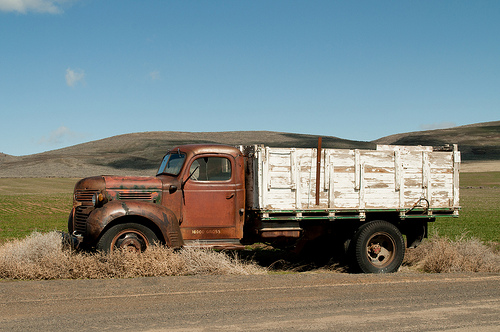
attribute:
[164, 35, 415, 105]
sky — deep, blue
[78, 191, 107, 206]
headlight — old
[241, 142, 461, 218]
truck bed — old, white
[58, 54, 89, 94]
cloud — white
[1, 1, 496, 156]
sky — blue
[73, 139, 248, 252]
cab — orange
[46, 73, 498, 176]
hill tops — very tall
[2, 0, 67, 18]
cloud — white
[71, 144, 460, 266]
truck — old, abandoned, parked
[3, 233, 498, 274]
grass — dead, dry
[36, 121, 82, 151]
cloud — white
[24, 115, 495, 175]
hills — grey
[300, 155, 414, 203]
wood — white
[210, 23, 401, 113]
sky — blue